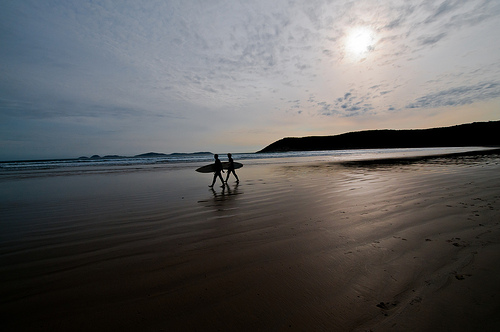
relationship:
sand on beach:
[44, 186, 433, 289] [24, 145, 491, 308]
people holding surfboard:
[189, 147, 270, 222] [189, 164, 249, 181]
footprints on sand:
[238, 172, 390, 221] [44, 186, 433, 289]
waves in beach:
[32, 158, 109, 172] [24, 145, 491, 308]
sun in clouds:
[339, 30, 390, 61] [260, 9, 487, 80]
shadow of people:
[185, 183, 242, 203] [189, 147, 270, 222]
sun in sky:
[339, 30, 390, 61] [43, 26, 420, 150]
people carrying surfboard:
[189, 147, 270, 222] [189, 164, 249, 181]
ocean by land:
[7, 143, 353, 183] [12, 161, 211, 202]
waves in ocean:
[32, 158, 109, 172] [7, 143, 353, 183]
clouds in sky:
[260, 9, 487, 80] [43, 26, 420, 150]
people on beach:
[189, 147, 270, 222] [24, 145, 491, 308]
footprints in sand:
[238, 172, 390, 221] [44, 186, 433, 289]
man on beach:
[207, 149, 227, 197] [24, 145, 491, 308]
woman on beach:
[222, 140, 254, 187] [24, 145, 491, 308]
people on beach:
[196, 152, 245, 188] [24, 145, 491, 308]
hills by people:
[265, 125, 499, 156] [189, 147, 270, 222]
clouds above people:
[260, 9, 487, 80] [189, 147, 270, 222]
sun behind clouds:
[339, 30, 390, 61] [260, 9, 487, 80]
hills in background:
[265, 125, 499, 156] [145, 19, 494, 164]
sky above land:
[43, 26, 420, 150] [12, 161, 211, 202]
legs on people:
[213, 170, 245, 187] [189, 147, 270, 222]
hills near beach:
[256, 120, 500, 153] [24, 145, 491, 308]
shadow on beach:
[185, 183, 242, 203] [24, 145, 491, 308]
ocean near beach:
[7, 143, 353, 183] [24, 145, 491, 308]